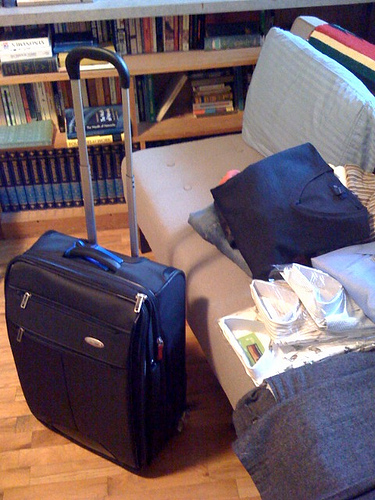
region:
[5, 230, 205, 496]
wood flooring of room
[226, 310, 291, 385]
white collared shirt in bag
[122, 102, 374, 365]
gray sofa on right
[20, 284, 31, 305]
metal zipper of luggage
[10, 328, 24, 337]
metal zipper of luggage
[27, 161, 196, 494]
a packed bag is on thr floor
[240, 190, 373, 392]
clothes are on the couch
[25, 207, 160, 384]
bag is blac kin color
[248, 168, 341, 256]
the top sweater is blacjk in color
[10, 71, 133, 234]
books are aranged o ths shelf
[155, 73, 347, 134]
couch is greay in color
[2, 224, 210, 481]
a small bag in ground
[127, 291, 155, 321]
a zip of the bag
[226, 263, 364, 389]
a group of shirts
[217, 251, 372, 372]
a series of shirts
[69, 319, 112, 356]
a logo to bag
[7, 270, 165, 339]
two zips of the bag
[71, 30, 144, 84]
a black top part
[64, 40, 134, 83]
black handle on suit case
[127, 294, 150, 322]
silver zipper on suitcase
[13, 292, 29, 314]
silver zipper on suit case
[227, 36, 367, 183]
white and blue striped pillow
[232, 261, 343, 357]
white folded shirts on couch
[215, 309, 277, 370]
white collar of shirt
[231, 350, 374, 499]
folded gray pants on a couch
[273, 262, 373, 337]
a packaged white shirt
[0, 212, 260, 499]
a light brown hardwood floor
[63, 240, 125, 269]
a blue tag on a suitcase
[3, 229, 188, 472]
a black suitcase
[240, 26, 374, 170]
a grey pillowcase on a couch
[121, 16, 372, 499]
a couch by a suitcase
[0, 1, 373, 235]
a bookshelf by a couch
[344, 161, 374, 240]
a folded striped shirt